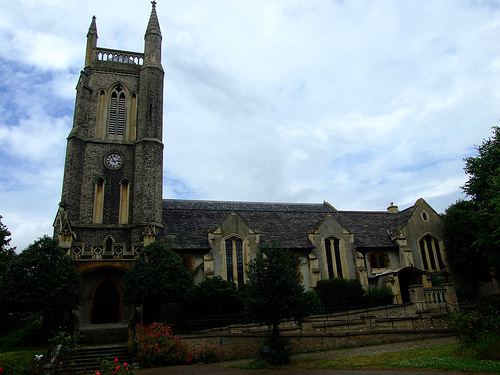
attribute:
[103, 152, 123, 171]
clock — white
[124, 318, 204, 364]
flowers — pink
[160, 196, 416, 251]
roof — dark gray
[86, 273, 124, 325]
doorway — arched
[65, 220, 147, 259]
wall — artistically designed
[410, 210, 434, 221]
window — small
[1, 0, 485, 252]
clouds — white 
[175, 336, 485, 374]
grass — green 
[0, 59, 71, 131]
sky — blue 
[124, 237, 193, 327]
tree — triangular 